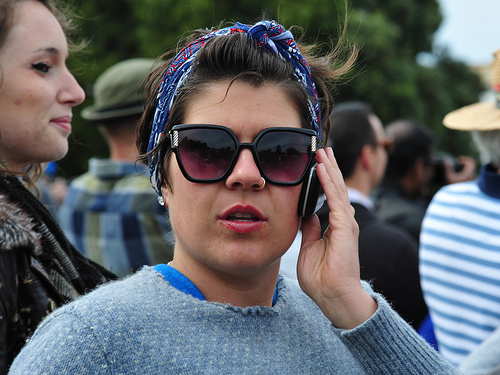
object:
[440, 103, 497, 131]
brim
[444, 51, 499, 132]
hat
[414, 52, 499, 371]
man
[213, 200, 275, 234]
mouth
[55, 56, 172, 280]
man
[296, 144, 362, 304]
woman's hand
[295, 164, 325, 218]
cellphone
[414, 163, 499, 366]
shirt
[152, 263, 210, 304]
tshirt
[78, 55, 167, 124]
green hat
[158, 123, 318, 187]
glasses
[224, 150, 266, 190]
nose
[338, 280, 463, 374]
sleeve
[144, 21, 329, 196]
bandana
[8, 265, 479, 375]
sweater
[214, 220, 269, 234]
lips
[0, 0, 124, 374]
woman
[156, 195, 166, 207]
earring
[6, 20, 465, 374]
woman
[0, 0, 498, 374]
crowd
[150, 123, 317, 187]
sunglasses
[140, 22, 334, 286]
head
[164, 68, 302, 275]
face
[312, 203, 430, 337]
suit coat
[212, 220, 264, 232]
lipstick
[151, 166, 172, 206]
woman's ear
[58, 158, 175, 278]
shirt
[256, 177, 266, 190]
nose ring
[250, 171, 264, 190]
nostril